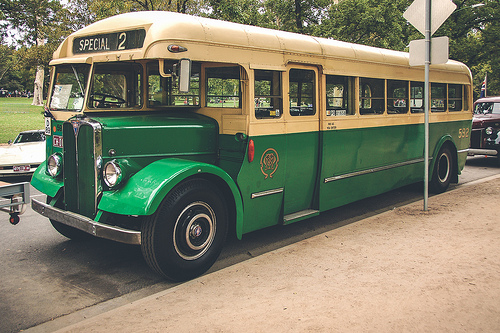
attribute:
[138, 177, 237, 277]
blackwheels — black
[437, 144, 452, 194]
blackwheels — black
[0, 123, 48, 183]
sports car — white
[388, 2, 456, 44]
sign — street traffic sign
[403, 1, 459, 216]
signs — metal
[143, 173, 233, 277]
wheel — rubber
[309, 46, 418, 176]
bus — tan and green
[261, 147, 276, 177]
logo — orange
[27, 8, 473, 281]
bus — public, green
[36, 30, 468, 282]
bus — white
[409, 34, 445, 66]
sign — traffic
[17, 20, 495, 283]
bus — vintage, green, tan